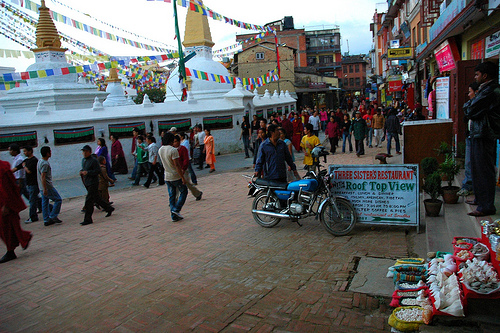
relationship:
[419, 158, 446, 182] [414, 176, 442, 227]
plants in pots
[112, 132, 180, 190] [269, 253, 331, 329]
people in walkway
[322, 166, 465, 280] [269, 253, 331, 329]
sign in walkway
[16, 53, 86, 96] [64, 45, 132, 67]
squares on rope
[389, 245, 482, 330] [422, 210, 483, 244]
baskets on staircase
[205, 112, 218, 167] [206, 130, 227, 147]
woman in orange